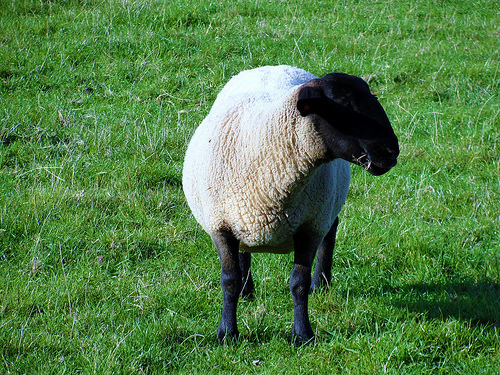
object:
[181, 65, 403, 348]
sheep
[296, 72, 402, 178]
head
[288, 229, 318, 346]
leg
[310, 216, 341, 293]
leg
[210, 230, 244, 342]
leg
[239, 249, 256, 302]
leg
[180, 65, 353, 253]
body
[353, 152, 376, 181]
grass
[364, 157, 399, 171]
mouth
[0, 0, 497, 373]
grass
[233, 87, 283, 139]
hair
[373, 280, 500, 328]
shadow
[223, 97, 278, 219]
wool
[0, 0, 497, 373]
field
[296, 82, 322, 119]
ear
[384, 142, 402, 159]
nose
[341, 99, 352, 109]
right eye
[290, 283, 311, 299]
knee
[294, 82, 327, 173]
neck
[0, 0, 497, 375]
ground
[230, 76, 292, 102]
sun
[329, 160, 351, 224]
back